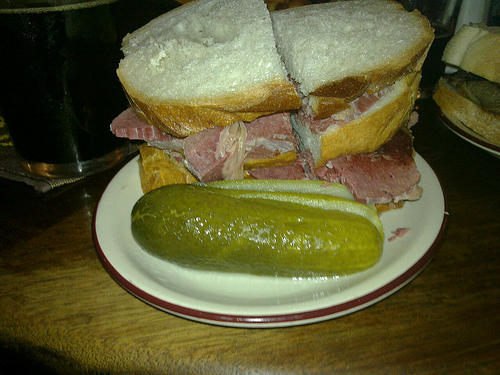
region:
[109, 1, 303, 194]
One half of a sandwich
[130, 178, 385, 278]
A sliced dill pickel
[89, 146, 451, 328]
A white plate with a red stripe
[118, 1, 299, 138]
A slice of white bread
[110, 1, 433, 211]
A double decker sandwhich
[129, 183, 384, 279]
A slice of pickel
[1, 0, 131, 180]
A glass of dark soda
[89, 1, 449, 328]
A full lunch plate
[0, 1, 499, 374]
A wooden table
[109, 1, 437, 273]
A meal at a restaurant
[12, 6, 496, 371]
A sandwich on the table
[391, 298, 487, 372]
The table is made of wood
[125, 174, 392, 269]
The pickle on the plate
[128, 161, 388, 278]
The pickle is the color green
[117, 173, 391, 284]
The pickle has been sliced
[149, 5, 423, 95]
The bread is white bread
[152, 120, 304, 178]
The meat on the sandwich is pink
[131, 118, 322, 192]
The meat on the sandwich is ham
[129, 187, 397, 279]
a pickel placed on a plate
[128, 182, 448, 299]
a picklet sitting next to a sandwhich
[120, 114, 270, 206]
meat sitting in two pieces of bread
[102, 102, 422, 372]
a plate of food sitting on a table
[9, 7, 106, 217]
a drink sitting on a table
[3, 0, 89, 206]
a filled glass sitting on a coaster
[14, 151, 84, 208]
a coaster sitting under a glass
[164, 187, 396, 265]
a pickle cut in three sections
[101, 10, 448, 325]
a big sandwich with a pickle on the side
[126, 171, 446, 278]
a green pickle on a plate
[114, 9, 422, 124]
a thick piece of white bread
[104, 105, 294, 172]
thick slices of ham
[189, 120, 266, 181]
the ham has fat on it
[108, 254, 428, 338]
the plate has a maroon stripe on the edge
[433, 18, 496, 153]
another sandwich in the picture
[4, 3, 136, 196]
a dark drink in a glass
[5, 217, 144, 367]
a wooden table to hold the food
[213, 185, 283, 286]
There is a large pickle here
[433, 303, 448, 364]
There is a dark-colored desk here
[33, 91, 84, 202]
There is a glass of beverage here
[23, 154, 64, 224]
There is a small tablecloth here